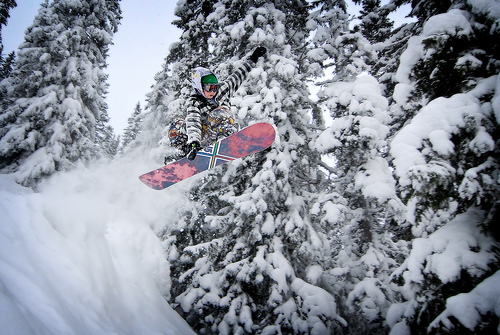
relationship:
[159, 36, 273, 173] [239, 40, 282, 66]
person wearing mittens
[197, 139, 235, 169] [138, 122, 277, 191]
colorful x underneath snowboard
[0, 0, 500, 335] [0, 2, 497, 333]
snow on trees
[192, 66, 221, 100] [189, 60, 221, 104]
head on person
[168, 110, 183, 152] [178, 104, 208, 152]
leg on person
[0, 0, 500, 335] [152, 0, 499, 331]
snow on tree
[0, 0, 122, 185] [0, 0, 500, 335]
snow on snow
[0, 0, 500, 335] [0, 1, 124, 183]
snow on tree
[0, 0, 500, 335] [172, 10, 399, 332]
snow on tree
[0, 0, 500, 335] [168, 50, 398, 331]
snow on tree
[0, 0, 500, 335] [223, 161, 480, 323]
snow on tree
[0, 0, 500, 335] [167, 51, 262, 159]
snow behind a person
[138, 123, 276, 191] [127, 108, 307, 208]
snowboard doing a jump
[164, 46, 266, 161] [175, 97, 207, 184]
person holding snowboard with ir right hand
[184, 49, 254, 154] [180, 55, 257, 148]
black and white plaid black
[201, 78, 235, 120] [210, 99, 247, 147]
ski goggles covering a persons eyes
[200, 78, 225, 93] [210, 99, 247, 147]
goggles goggles covering a persons eyes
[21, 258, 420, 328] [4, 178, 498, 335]
snow covering ground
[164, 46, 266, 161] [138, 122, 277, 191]
person on top of a snowboard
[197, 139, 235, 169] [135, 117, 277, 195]
colorful x printed on snowboard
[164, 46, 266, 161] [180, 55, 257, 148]
person wearing a striped black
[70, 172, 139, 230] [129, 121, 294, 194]
plume of white snow behind snowboard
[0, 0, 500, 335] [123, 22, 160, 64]
snow tree in front of sky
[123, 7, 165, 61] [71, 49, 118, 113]
sky behind tree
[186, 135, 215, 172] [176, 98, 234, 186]
feet of a person